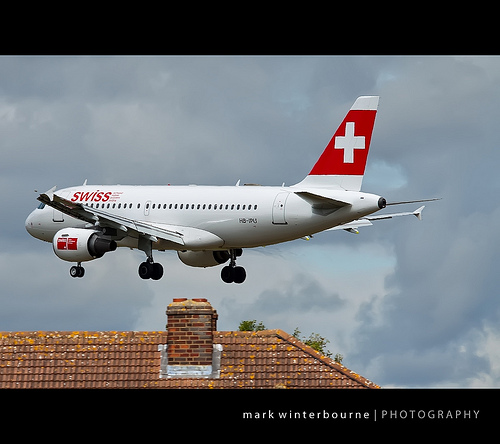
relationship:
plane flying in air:
[25, 95, 442, 282] [0, 55, 499, 389]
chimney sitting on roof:
[166, 297, 219, 379] [1, 330, 382, 389]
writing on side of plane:
[72, 191, 113, 202] [25, 95, 442, 282]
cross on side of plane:
[334, 122, 365, 164] [25, 95, 442, 282]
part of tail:
[307, 111, 377, 175] [291, 95, 379, 191]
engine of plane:
[52, 226, 118, 261] [25, 95, 442, 282]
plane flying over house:
[25, 95, 442, 282] [0, 298, 384, 390]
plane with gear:
[25, 95, 442, 282] [220, 248, 247, 282]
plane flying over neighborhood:
[25, 95, 442, 282] [0, 319, 383, 388]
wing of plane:
[294, 190, 351, 206] [25, 95, 442, 282]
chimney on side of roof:
[166, 297, 219, 379] [1, 330, 382, 389]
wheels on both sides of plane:
[139, 262, 165, 281] [25, 95, 442, 282]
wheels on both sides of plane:
[221, 265, 247, 283] [25, 95, 442, 282]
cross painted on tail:
[334, 122, 365, 164] [291, 95, 379, 191]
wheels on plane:
[68, 266, 86, 278] [25, 95, 442, 282]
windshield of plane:
[37, 200, 45, 209] [25, 95, 442, 282]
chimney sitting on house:
[166, 297, 219, 379] [0, 298, 384, 390]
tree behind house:
[239, 319, 344, 363] [0, 298, 384, 390]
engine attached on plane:
[52, 226, 118, 261] [25, 95, 442, 282]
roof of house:
[1, 330, 382, 389] [0, 298, 384, 390]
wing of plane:
[37, 191, 223, 250] [25, 95, 442, 282]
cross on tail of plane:
[334, 122, 365, 164] [25, 95, 442, 282]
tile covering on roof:
[12, 358, 40, 368] [1, 330, 382, 389]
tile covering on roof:
[54, 366, 78, 374] [1, 330, 382, 389]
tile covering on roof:
[141, 366, 162, 374] [1, 330, 382, 389]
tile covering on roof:
[244, 357, 258, 367] [1, 330, 382, 389]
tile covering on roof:
[308, 371, 325, 378] [1, 330, 382, 389]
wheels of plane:
[139, 262, 165, 281] [25, 95, 442, 282]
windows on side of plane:
[78, 203, 134, 208] [25, 95, 442, 282]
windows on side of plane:
[145, 202, 259, 211] [25, 95, 442, 282]